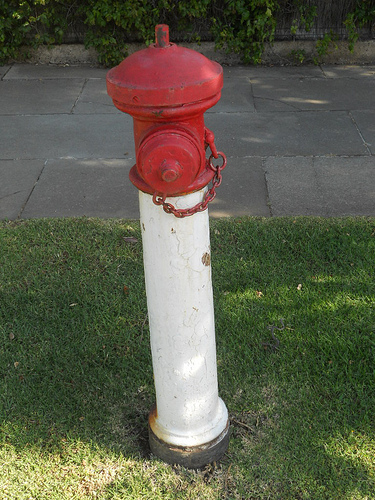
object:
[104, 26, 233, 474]
hydrant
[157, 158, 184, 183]
bolt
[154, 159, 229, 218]
chain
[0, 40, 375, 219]
cement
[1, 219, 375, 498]
grass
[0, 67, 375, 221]
sidewalk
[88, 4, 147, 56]
plants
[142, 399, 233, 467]
base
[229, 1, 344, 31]
leaves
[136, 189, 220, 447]
pole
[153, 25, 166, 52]
rust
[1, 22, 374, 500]
ground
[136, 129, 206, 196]
nob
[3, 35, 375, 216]
concrete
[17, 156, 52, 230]
cracks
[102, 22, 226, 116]
top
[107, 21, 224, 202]
paint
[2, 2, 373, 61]
bushes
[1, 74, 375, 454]
shadow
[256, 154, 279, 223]
crack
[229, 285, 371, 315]
light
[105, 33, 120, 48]
leaf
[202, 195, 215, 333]
edge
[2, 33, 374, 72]
curb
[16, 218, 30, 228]
piece